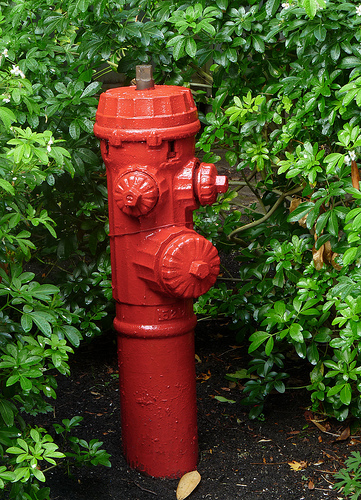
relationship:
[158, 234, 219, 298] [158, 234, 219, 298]
cover over cover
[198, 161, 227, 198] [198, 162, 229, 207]
cover over cover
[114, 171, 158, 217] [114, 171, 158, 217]
cover over cover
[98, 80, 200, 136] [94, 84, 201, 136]
cover over cover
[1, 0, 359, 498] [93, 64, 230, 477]
bushes around fire hydrant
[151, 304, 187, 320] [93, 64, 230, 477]
number on fire hydrant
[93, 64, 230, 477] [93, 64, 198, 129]
fire hydrant has top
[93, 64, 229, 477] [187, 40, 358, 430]
fire hydrant among bush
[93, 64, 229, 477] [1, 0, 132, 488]
fire hydrant among bush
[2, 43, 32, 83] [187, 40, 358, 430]
flowers in bush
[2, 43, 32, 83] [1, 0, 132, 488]
flowers in bush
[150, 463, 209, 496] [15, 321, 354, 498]
leaf on ground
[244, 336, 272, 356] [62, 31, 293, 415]
leaf behind hydrant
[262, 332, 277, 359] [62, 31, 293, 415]
leaf behind hydrant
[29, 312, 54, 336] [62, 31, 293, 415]
leaf behind hydrant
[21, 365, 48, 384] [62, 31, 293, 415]
leaf behind hydrant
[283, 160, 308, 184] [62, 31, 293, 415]
leaf behind hydrant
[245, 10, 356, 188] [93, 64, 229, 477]
leaves are behind fire hydrant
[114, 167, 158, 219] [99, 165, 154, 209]
cover over port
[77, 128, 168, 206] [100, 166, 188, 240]
cover over port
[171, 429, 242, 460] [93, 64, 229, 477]
dirt around fire hydrant